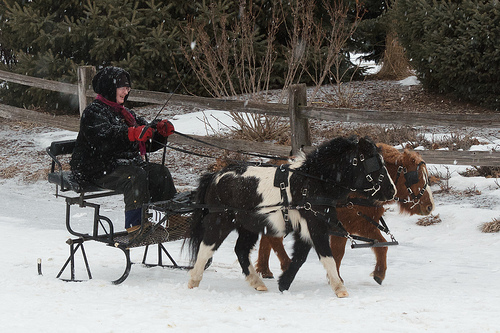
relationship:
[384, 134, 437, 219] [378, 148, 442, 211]
horse has head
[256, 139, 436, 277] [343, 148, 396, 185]
horse has eye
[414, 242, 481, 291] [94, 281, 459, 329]
snow on ground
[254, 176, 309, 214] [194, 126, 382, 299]
spot on horse